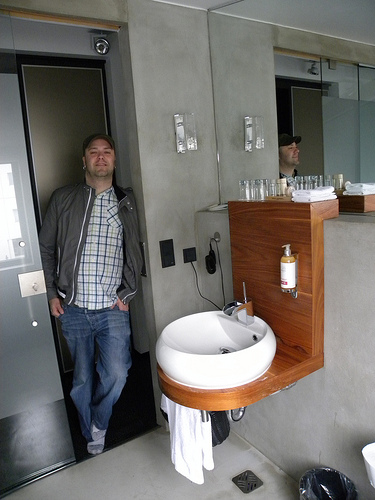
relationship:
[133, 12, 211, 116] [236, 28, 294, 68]
wall inside house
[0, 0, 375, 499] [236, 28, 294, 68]
wall inside house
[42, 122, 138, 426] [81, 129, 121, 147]
man wears cap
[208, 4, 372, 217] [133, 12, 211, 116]
mirror on wall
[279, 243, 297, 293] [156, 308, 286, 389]
soap above sink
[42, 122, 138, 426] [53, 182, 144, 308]
man wears jacket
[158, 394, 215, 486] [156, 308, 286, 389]
towel under sink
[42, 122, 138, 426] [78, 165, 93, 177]
man wears earring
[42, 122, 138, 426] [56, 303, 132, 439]
man wears blue jeans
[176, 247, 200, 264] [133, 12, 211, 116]
socket in wall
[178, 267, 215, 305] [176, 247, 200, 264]
wire in socket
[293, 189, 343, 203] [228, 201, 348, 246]
towels on shelf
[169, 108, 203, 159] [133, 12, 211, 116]
light on wall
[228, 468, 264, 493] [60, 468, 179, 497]
drain on floor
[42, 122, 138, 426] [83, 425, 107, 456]
man wears socks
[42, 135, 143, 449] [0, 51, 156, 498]
man standing on door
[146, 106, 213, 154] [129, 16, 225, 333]
glass on wall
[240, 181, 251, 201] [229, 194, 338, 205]
glasses in shelf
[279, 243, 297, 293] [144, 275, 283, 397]
soap in sink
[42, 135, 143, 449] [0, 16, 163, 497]
man leaning in doorway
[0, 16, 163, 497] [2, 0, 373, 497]
doorway in bathroom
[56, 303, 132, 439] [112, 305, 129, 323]
blue jeans with pocket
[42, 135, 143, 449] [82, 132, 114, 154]
man with cap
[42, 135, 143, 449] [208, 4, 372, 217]
man reflecting in mirror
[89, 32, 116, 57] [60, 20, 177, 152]
camera on background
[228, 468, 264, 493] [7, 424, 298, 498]
drain in floor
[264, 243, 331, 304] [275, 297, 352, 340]
soap on wall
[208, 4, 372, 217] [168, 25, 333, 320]
mirror on a wall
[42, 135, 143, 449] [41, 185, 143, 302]
man in a jacket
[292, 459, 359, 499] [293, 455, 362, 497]
bin lined with plastic